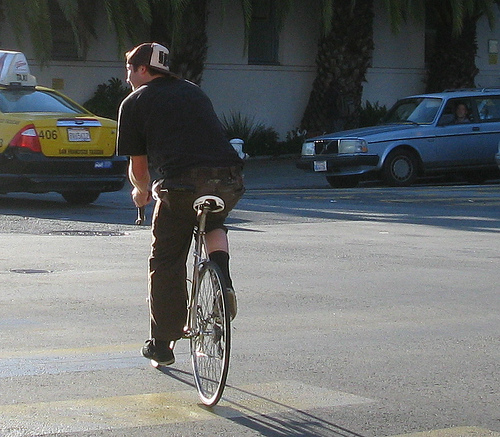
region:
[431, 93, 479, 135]
man driving a car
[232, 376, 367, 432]
shadow of bicycle on pavement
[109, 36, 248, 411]
guy riding a bicycle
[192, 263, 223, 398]
bicycle wheel spokes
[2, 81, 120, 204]
back of yellow taxi cab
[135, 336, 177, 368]
black men's shoe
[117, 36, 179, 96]
baseball cap being worn backwards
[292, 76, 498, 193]
blue car at intersection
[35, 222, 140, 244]
round metal manhole cover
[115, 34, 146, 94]
man with sun on his face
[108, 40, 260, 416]
Person riding a bicycle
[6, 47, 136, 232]
Taxi cab on the street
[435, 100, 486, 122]
Person driving a car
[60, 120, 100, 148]
License plate on taxi cab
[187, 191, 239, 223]
Seat on bicycle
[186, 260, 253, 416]
Back tire of bicycle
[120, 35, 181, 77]
Cap on persons head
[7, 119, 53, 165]
Tail light on taxi cab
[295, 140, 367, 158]
Headlights and grill on front of car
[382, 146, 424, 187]
Tire on car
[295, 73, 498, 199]
a blue car on the road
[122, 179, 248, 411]
a bicycle on a road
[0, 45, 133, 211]
a yellow taxi on a road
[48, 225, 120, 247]
a manhole cover in a road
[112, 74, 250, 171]
a black shirt on a man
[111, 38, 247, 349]
a man on a bike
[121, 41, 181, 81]
a cap on a man's head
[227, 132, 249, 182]
a fire hydrant alongside a road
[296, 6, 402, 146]
the trunk of a tree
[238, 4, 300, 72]
a window in a building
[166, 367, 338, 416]
large shadow on the street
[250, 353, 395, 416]
large white line on the street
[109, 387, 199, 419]
brown smudge on the street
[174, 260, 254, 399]
large wheel on bike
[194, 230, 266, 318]
man wearing black socks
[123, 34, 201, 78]
red and white cap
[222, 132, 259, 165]
white fire hydrant on side walk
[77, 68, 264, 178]
man wearing black shirt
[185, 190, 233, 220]
white wheel on bike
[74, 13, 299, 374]
man riding bike on street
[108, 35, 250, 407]
a man riding a bicycle in the street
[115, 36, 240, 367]
a man wearing a brown and white cap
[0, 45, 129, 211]
a yellow taxi cab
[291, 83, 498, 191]
a light blue car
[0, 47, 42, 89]
a mounted car top sign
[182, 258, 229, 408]
a bicycle's rear tire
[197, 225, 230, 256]
a man's bare leg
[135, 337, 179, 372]
a black and white tennis shoe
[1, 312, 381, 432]
yellow cross walk markers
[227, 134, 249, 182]
a white fire hydrant